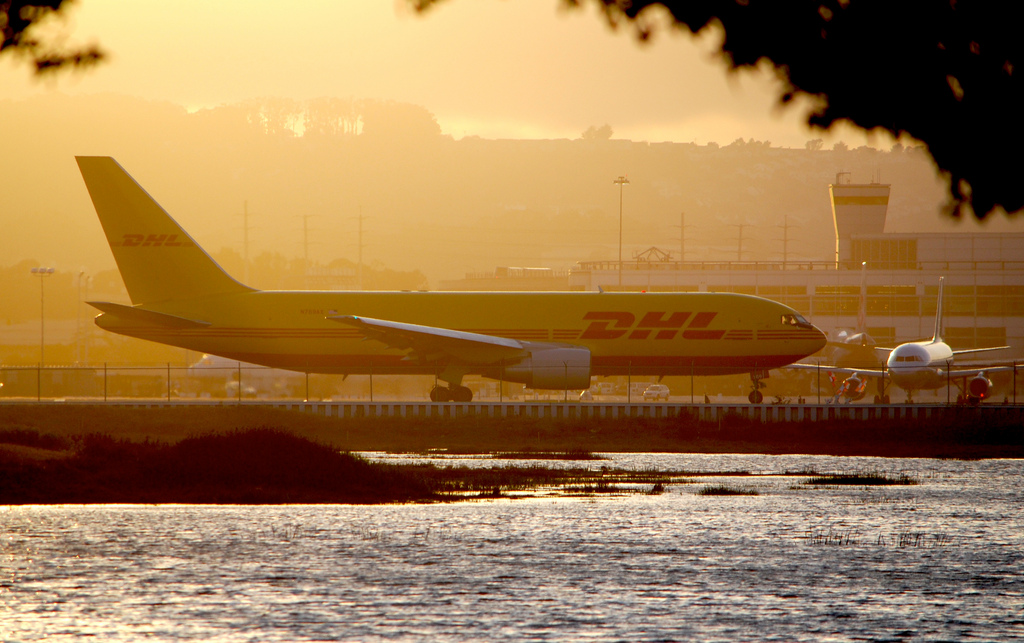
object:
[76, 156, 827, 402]
plane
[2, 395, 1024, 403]
runway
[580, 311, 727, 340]
sign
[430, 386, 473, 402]
wheels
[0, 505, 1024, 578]
sunlight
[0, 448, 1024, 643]
water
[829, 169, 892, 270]
tower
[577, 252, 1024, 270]
top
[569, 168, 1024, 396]
building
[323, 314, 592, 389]
wing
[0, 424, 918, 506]
grass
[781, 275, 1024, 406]
plane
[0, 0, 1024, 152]
sky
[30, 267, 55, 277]
lights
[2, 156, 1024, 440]
airport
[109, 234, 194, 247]
logo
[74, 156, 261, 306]
tail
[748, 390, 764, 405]
wheels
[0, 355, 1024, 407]
fence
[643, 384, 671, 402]
car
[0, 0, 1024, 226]
foliage